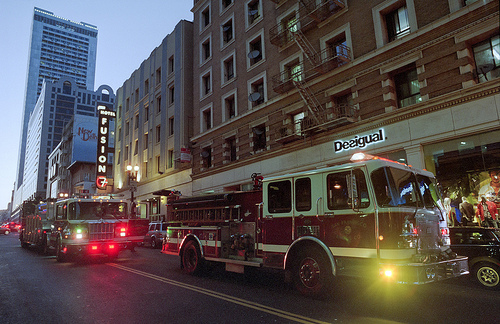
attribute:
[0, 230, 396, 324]
street — divided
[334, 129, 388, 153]
sign — lit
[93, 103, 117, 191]
text — white, black, bright, attached, lit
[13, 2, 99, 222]
building — tall, towering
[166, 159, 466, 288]
truck — red, white, firetruck, big, moving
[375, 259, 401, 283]
light — yellow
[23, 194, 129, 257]
truck — red, white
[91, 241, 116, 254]
light — red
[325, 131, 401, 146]
text — black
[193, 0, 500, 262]
building — cement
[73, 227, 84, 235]
light — green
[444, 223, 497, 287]
vehicle — parked, black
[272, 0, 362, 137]
stairs — metal, exit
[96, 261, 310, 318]
divider — yellow, double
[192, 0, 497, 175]
windows — lit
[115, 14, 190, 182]
stripes — vertical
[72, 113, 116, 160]
advertisement — large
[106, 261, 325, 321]
stripe — yellow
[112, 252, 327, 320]
stripe — yellow